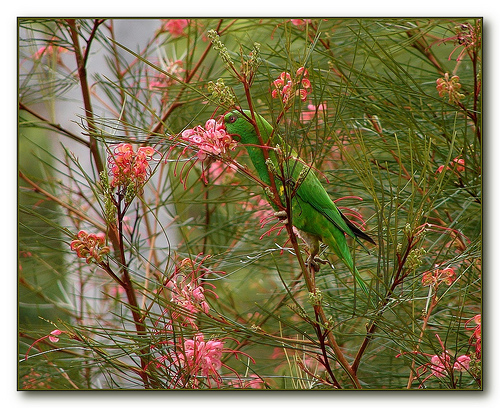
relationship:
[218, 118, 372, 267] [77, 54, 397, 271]
bird near flowers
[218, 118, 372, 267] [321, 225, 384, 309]
bird has tail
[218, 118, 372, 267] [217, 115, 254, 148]
bird has head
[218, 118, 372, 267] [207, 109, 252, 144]
bird has face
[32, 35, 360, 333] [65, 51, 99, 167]
tree has stick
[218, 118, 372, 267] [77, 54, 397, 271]
bird eating flowers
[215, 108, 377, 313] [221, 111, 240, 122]
bird has eye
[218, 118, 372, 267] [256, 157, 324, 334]
bird on top of branch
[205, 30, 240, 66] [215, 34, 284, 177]
buds growing on twigs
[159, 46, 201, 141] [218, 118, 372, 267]
branch in front of bird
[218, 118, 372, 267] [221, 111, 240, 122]
bird has eye